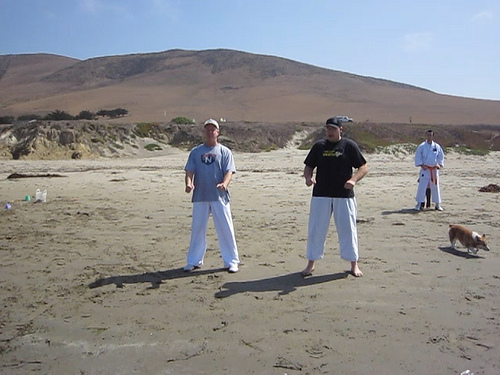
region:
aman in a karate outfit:
[406, 119, 478, 242]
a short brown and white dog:
[426, 218, 498, 255]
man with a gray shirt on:
[173, 104, 255, 296]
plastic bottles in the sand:
[18, 172, 58, 231]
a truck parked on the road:
[321, 108, 373, 138]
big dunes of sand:
[157, 33, 392, 142]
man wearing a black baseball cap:
[314, 109, 357, 140]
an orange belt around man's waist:
[407, 157, 466, 190]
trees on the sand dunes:
[42, 99, 146, 124]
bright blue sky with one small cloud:
[6, 13, 495, 90]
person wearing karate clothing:
[407, 122, 447, 214]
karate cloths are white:
[409, 125, 450, 213]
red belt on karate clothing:
[411, 125, 448, 214]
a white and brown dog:
[441, 219, 492, 261]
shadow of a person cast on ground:
[211, 270, 303, 304]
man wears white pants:
[292, 110, 373, 281]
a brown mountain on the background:
[0, 41, 493, 136]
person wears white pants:
[171, 111, 246, 282]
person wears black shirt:
[297, 108, 376, 213]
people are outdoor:
[103, 107, 453, 299]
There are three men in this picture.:
[178, 110, 446, 285]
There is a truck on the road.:
[333, 111, 355, 124]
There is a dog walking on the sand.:
[447, 221, 491, 259]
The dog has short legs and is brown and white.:
[447, 221, 489, 258]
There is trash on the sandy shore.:
[2, 189, 49, 211]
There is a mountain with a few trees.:
[4, 46, 498, 124]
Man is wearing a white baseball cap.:
[183, 116, 238, 274]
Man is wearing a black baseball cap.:
[301, 116, 369, 281]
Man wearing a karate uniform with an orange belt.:
[414, 128, 444, 215]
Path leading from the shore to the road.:
[280, 121, 315, 156]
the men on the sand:
[179, 120, 371, 285]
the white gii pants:
[188, 203, 240, 268]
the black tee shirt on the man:
[305, 138, 368, 199]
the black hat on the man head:
[322, 115, 339, 128]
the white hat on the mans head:
[200, 118, 219, 131]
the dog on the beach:
[442, 219, 492, 261]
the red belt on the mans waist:
[422, 162, 441, 188]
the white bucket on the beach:
[34, 185, 48, 204]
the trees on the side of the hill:
[45, 105, 133, 120]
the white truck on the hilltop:
[337, 113, 356, 124]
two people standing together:
[158, 71, 380, 312]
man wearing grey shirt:
[185, 140, 238, 202]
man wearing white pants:
[173, 188, 245, 264]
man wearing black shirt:
[300, 135, 374, 200]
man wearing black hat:
[320, 113, 345, 133]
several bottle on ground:
[10, 164, 58, 218]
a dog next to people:
[432, 204, 492, 279]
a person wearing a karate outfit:
[407, 132, 452, 208]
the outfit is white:
[407, 141, 449, 211]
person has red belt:
[410, 162, 445, 184]